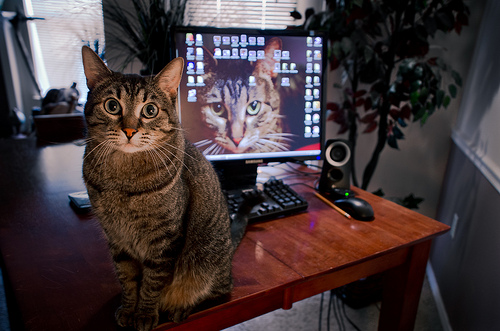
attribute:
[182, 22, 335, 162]
monitor — black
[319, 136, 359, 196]
webcam — black, silver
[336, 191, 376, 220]
mouse — black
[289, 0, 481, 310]
tree — green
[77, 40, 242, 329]
cat — brown, black, adult